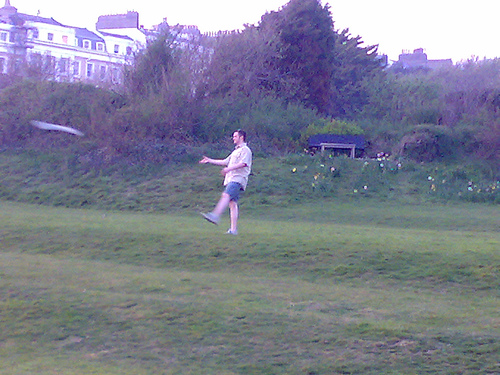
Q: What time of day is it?
A: Daytime.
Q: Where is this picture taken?
A: Park.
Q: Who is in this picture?
A: A man.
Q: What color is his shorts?
A: Blue.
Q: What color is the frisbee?
A: White.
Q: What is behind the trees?
A: Houses.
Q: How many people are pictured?
A: One.